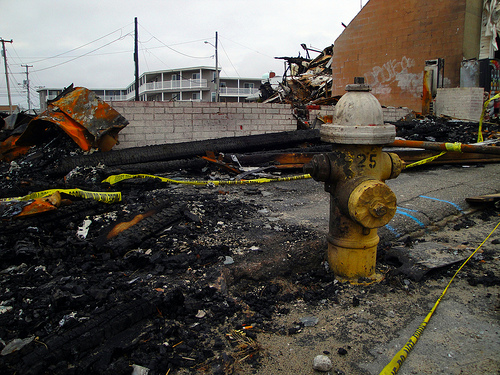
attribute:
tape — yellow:
[4, 142, 469, 193]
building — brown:
[35, 61, 265, 109]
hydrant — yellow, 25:
[312, 79, 413, 279]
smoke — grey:
[459, 62, 480, 93]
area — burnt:
[97, 201, 208, 266]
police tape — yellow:
[381, 221, 498, 373]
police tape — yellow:
[3, 186, 125, 211]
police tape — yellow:
[102, 171, 314, 184]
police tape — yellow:
[404, 142, 460, 167]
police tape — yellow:
[478, 93, 498, 140]